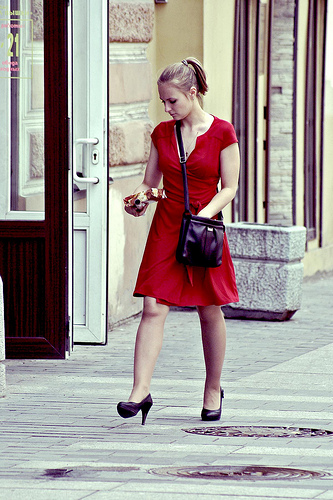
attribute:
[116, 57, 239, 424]
woman — walking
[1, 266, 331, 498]
sidewalk — gray, tiled cement, stone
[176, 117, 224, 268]
purse — black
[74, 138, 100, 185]
handle — white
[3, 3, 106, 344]
door — open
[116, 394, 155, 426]
heel — black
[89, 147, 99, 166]
keyhole — old fashion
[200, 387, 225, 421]
heel — black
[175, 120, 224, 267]
bag — black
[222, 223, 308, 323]
recepticle — cement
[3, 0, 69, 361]
door — wooden, dark wood, open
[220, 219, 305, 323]
trash can — concrete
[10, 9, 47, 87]
writing — yellow, pink